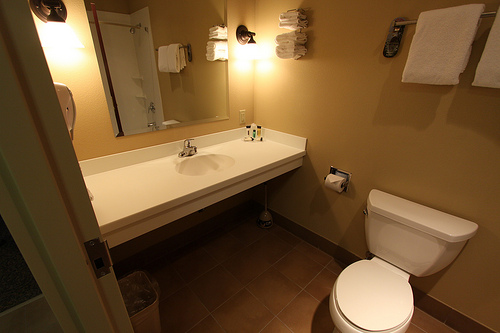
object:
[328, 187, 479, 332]
toilet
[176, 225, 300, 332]
tile floor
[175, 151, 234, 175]
sink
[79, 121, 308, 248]
counter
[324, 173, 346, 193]
toilet paper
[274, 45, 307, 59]
towels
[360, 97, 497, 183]
wall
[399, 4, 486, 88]
towels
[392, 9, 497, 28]
rack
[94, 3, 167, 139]
shower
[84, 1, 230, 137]
mirror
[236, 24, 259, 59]
light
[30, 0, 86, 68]
light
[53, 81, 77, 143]
soap dispenser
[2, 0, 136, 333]
wall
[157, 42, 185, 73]
towels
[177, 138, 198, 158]
faucet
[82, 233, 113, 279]
door latch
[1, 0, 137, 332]
door frame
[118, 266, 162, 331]
trashcan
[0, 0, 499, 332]
bathroom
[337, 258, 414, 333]
lid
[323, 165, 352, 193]
holder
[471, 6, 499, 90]
towel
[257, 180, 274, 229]
toilet brush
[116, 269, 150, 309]
liner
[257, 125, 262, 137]
toiletries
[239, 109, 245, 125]
light switch